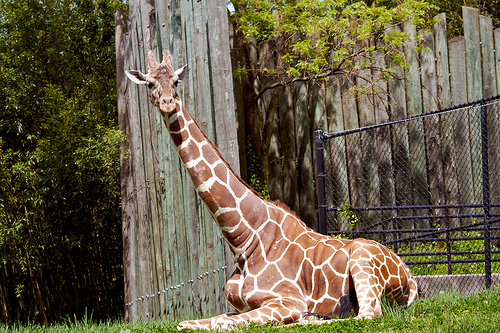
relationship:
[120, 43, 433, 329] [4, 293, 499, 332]
giraffe on ground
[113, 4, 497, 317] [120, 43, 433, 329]
fence behind giraffe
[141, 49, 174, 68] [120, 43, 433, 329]
horns on giraffe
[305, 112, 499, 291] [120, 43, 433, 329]
gate behind giraffe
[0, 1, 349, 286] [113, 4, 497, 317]
trees behind fence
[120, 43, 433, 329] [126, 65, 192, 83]
giraffe has ears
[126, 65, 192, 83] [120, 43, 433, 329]
ears on giraffe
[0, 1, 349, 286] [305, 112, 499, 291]
trees behind gate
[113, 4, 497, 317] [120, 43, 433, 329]
fence besides giraffe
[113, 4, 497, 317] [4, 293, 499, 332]
fence on ground